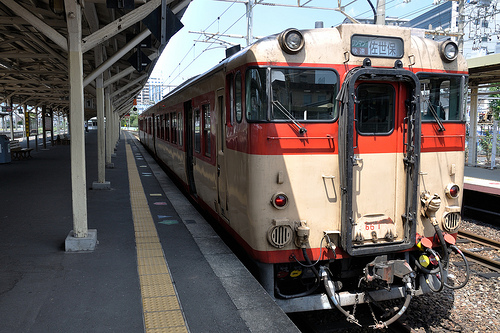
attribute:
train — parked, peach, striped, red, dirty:
[134, 22, 476, 331]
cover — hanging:
[0, 2, 192, 119]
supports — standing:
[3, 1, 161, 265]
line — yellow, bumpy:
[118, 133, 194, 332]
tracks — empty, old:
[458, 220, 498, 282]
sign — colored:
[22, 110, 42, 139]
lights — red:
[268, 183, 464, 211]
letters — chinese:
[348, 31, 407, 60]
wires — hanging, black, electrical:
[147, 1, 267, 104]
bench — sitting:
[9, 137, 31, 159]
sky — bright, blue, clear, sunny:
[112, 1, 447, 97]